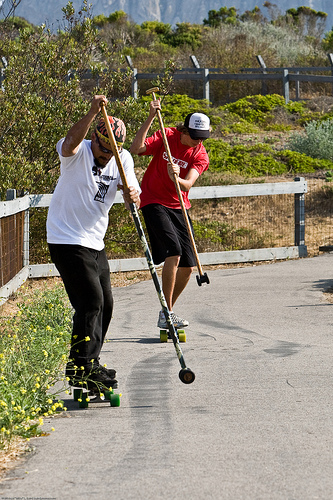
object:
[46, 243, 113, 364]
black pants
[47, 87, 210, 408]
player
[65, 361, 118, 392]
black shoes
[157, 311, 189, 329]
shoes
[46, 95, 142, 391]
man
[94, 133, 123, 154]
glasses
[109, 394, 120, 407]
wheels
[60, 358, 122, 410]
skateboard